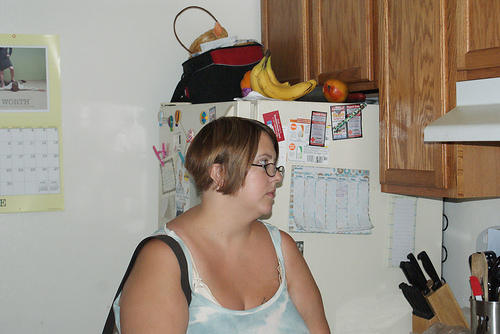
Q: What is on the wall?
A: A calendar.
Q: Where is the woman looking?
A: At the cabinet.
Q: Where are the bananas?
A: On top of the fridge.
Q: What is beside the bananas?
A: An apple.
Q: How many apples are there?
A: One.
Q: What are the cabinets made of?
A: Wood.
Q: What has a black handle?
A: Knives.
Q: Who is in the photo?
A: A woman.